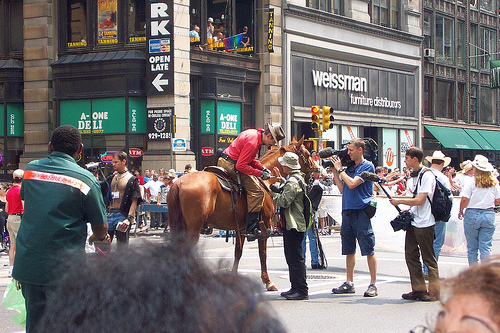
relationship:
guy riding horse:
[214, 118, 289, 242] [154, 129, 351, 269]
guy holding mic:
[357, 110, 487, 282] [353, 160, 410, 223]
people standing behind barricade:
[132, 165, 177, 230] [132, 203, 169, 230]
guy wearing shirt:
[15, 122, 111, 329] [16, 151, 105, 284]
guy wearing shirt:
[214, 103, 290, 233] [223, 125, 270, 174]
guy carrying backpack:
[389, 137, 446, 305] [402, 155, 455, 295]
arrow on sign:
[150, 73, 172, 88] [144, 73, 183, 95]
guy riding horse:
[218, 122, 286, 241] [162, 136, 326, 296]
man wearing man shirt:
[222, 123, 274, 177] [215, 118, 282, 193]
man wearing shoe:
[326, 137, 383, 297] [329, 280, 355, 295]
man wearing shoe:
[326, 137, 383, 297] [362, 280, 380, 297]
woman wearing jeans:
[445, 143, 499, 298] [461, 202, 498, 268]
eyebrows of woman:
[428, 301, 498, 329] [427, 264, 497, 330]